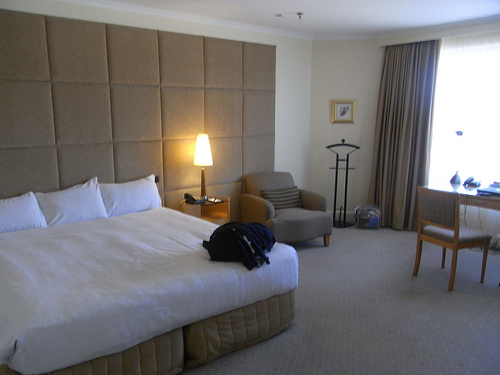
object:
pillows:
[0, 172, 163, 232]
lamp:
[186, 129, 224, 201]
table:
[177, 188, 234, 222]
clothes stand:
[323, 136, 356, 230]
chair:
[407, 185, 493, 293]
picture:
[328, 96, 358, 127]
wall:
[3, 44, 332, 182]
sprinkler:
[289, 6, 311, 25]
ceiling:
[40, 0, 500, 47]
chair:
[238, 166, 339, 251]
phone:
[460, 174, 485, 193]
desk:
[412, 171, 499, 251]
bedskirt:
[11, 290, 305, 375]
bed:
[0, 178, 299, 372]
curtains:
[364, 36, 443, 232]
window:
[417, 39, 499, 194]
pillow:
[251, 179, 307, 210]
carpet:
[299, 292, 494, 374]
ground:
[296, 246, 499, 375]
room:
[0, 1, 500, 375]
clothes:
[200, 214, 279, 276]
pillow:
[32, 177, 112, 228]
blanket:
[0, 205, 295, 374]